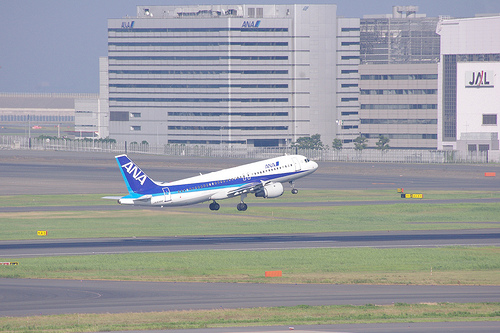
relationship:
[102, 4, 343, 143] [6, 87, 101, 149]
building next to airport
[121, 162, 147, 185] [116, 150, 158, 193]
ana on tail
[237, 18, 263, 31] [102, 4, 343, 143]
name written on building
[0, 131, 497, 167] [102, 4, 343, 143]
fence next to building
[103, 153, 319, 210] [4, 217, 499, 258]
airplane on runway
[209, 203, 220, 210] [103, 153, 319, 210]
gear on airplane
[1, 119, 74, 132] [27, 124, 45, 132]
road for cars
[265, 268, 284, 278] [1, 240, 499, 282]
symbol on grass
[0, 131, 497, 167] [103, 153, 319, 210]
fence front of airplane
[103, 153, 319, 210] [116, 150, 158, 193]
airplane has tail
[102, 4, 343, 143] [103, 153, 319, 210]
building left of airplane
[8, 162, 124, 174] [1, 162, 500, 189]
shadow on street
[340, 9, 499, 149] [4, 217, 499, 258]
buildings next to runway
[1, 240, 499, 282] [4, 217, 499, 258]
grass next to runway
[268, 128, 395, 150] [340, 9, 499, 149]
trees front of buildings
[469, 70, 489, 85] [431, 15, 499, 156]
lettering on building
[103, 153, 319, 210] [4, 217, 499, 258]
airplane off runway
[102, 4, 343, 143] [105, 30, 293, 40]
building with level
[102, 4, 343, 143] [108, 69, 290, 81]
building with level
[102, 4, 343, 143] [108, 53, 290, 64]
building with level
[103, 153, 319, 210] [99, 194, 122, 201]
airplane has wing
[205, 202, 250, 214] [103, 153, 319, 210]
gear on airplane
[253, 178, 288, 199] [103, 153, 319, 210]
engine on airplane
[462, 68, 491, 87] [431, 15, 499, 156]
lettering on building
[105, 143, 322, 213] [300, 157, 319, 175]
airplane has nose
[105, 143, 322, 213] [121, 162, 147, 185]
airplane with ana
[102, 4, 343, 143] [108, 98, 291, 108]
building has floor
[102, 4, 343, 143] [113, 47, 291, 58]
building has floor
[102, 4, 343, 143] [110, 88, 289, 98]
building has floor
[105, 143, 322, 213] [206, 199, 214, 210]
airplane has wheel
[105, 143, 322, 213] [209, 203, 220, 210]
airplane has gear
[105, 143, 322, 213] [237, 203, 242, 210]
airplane has wheel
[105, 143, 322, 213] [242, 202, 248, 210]
airplane has wheel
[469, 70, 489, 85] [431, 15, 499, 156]
lettering front of building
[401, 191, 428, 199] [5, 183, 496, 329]
object on field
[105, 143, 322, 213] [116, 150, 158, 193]
airplane has tail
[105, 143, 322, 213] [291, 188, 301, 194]
airplane has wheel